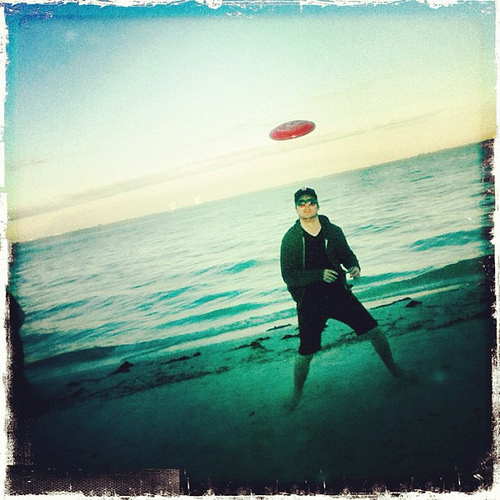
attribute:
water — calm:
[5, 137, 493, 375]